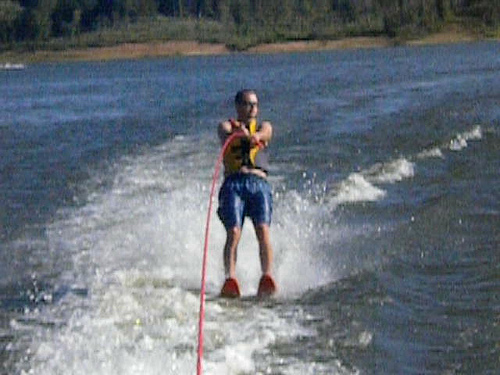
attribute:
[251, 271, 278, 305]
water ski — red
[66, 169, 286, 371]
water — rough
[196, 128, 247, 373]
tow line — red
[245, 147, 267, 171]
life jacket — yellow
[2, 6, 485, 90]
vegetation — dense 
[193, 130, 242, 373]
rope — red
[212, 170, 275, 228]
trunks — blue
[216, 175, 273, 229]
shorts — blue